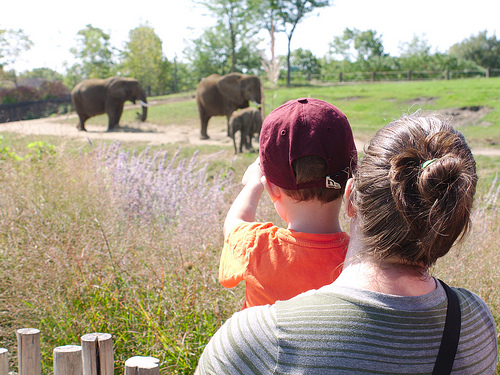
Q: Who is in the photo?
A: Two people.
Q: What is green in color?
A: The grass.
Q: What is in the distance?
A: Trees.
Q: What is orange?
A: The shirt.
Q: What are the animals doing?
A: Standing.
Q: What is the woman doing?
A: Holding a boy.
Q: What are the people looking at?
A: Elephants.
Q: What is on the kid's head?
A: Baseball hat.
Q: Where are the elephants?
A: In a field.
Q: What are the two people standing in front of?
A: Wooden fence.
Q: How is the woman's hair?
A: In a bun.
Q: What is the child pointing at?
A: Baby elephant.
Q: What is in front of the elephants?
A: Dried grass.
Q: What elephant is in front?
A: Baby elephant.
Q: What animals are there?
A: Elephants.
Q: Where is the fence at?
A: Next to the people.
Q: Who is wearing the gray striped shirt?
A: The girl holding the child.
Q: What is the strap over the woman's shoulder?
A: A black one.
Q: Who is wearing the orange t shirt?
A: The boy.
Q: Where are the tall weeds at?
A: By the elephants.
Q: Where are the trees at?
A: Behind the elephants.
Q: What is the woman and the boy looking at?
A: Elephants.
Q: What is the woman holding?
A: A boy.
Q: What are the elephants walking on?
A: Dirt path.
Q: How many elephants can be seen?
A: Three.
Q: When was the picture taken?
A: Daytime.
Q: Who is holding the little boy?
A: A woman.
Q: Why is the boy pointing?
A: Looking at the elephants.